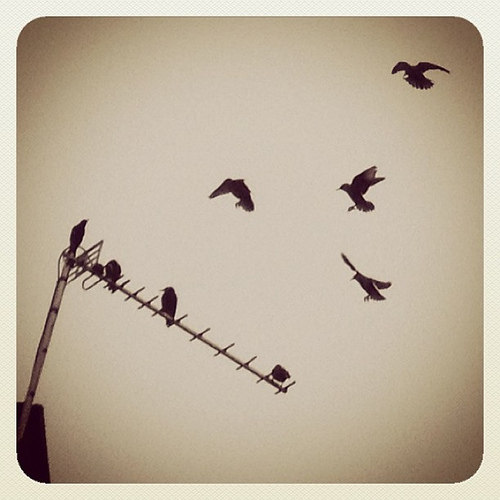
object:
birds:
[159, 286, 177, 328]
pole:
[18, 247, 76, 441]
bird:
[391, 58, 450, 90]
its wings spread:
[416, 61, 450, 73]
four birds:
[208, 61, 450, 299]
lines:
[188, 327, 211, 340]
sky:
[16, 14, 484, 485]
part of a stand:
[18, 222, 297, 453]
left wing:
[418, 61, 450, 74]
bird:
[270, 364, 291, 385]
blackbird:
[66, 217, 89, 258]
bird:
[208, 176, 253, 211]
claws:
[234, 199, 242, 207]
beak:
[402, 71, 409, 80]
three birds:
[335, 61, 451, 299]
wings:
[208, 179, 230, 199]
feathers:
[352, 175, 385, 194]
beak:
[159, 288, 167, 293]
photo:
[16, 15, 483, 482]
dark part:
[378, 391, 483, 482]